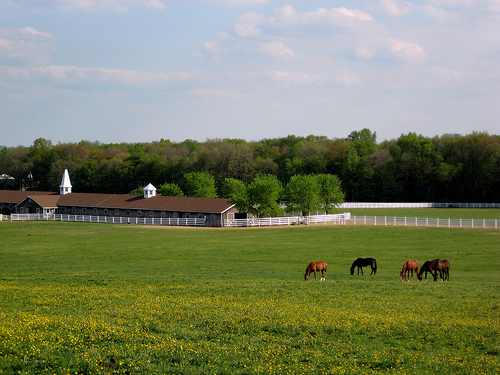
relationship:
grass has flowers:
[4, 220, 499, 374] [4, 298, 121, 363]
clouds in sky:
[247, 10, 410, 61] [0, 3, 499, 139]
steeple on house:
[59, 165, 73, 194] [3, 169, 260, 230]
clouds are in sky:
[247, 10, 410, 61] [0, 3, 499, 139]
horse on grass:
[303, 261, 328, 280] [4, 220, 499, 374]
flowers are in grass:
[4, 298, 121, 363] [4, 220, 499, 374]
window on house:
[160, 211, 166, 218] [3, 169, 260, 230]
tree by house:
[317, 174, 345, 218] [3, 169, 260, 230]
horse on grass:
[351, 259, 378, 275] [4, 220, 499, 374]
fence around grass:
[8, 210, 490, 235] [4, 220, 499, 374]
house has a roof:
[3, 169, 260, 230] [1, 191, 253, 214]